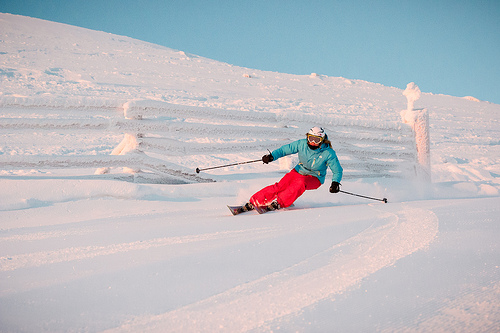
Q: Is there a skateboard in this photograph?
A: No, there are no skateboards.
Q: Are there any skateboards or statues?
A: No, there are no skateboards or statues.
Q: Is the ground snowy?
A: Yes, the ground is snowy.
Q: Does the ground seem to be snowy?
A: Yes, the ground is snowy.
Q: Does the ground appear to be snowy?
A: Yes, the ground is snowy.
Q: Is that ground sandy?
A: No, the ground is snowy.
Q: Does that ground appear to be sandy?
A: No, the ground is snowy.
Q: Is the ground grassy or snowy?
A: The ground is snowy.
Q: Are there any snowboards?
A: No, there are no snowboards.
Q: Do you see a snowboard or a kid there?
A: No, there are no snowboards or children.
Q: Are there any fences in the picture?
A: Yes, there is a fence.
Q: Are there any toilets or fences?
A: Yes, there is a fence.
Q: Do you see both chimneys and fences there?
A: No, there is a fence but no chimneys.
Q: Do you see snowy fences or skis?
A: Yes, there is a snowy fence.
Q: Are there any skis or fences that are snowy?
A: Yes, the fence is snowy.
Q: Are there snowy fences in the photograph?
A: Yes, there is a snowy fence.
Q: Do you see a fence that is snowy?
A: Yes, there is a fence that is snowy.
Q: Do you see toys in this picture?
A: No, there are no toys.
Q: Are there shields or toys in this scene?
A: No, there are no toys or shields.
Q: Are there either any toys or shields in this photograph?
A: No, there are no toys or shields.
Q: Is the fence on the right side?
A: No, the fence is on the left of the image.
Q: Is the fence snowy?
A: Yes, the fence is snowy.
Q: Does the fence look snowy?
A: Yes, the fence is snowy.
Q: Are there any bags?
A: No, there are no bags.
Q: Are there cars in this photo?
A: No, there are no cars.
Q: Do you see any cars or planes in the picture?
A: No, there are no cars or planes.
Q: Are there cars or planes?
A: No, there are no cars or planes.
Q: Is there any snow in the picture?
A: Yes, there is snow.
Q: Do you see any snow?
A: Yes, there is snow.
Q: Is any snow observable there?
A: Yes, there is snow.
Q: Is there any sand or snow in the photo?
A: Yes, there is snow.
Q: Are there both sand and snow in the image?
A: No, there is snow but no sand.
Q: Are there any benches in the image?
A: No, there are no benches.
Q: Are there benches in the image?
A: No, there are no benches.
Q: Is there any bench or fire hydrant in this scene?
A: No, there are no benches or fire hydrants.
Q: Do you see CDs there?
A: No, there are no cds.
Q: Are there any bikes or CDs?
A: No, there are no CDs or bikes.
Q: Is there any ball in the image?
A: No, there are no balls.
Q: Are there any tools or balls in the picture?
A: No, there are no balls or tools.